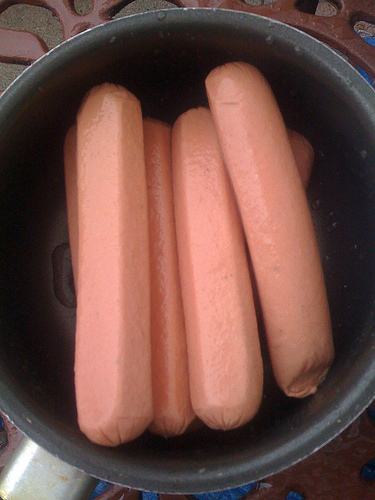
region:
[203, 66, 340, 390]
this is a sausage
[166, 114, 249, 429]
this is a sausage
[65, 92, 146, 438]
this is a sausage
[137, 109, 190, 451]
this is a sausage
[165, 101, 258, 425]
this is a sausage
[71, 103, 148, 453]
this is sausage is brown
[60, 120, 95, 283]
this is sausage is brown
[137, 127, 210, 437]
this is sausage is brown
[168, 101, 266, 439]
this is sausage is brown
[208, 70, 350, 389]
this is sausage is brown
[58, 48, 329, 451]
a pile of hot dogs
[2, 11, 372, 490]
raw hot dogs in a pot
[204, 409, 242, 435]
lines on the bottom of the wiener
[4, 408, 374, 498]
edge of the pot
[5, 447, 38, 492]
light glare on the silver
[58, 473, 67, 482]
brown mark on the silver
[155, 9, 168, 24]
water droplet on the pot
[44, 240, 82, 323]
glob of water in the pot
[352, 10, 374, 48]
hole in the plastic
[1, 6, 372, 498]
black pot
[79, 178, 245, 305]
Sausages on the bowl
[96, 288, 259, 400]
raw sausages on the bowl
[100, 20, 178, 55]
A bowl in the photo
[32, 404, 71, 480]
A pan in the photo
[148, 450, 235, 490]
A black bowl in the photo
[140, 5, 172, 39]
Water drops on the container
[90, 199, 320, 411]
Raw sausages in the picture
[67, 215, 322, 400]
Sausage rolls in the photo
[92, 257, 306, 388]
Rolls of sausage in the picture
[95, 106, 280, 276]
Hotdogs in the photo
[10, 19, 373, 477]
The hotdogs are inside a pan.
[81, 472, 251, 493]
The flame is turned on.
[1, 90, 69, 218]
The pan is black.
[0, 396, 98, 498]
The pan has a silver handle.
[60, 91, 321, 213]
Six hotdogs are cooking in a pan.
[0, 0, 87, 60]
The stove is made out of a red metal.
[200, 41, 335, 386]
The hotdog is big.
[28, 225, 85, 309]
A water droplet is inside of the pan.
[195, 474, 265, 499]
The flame is blue.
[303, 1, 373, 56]
The stove has water on top of it.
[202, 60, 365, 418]
this is a sausage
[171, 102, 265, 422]
this is a sausage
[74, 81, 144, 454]
this is a sausage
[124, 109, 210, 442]
this is a sausage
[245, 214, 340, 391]
this is a sausage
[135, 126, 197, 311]
this is a sausage